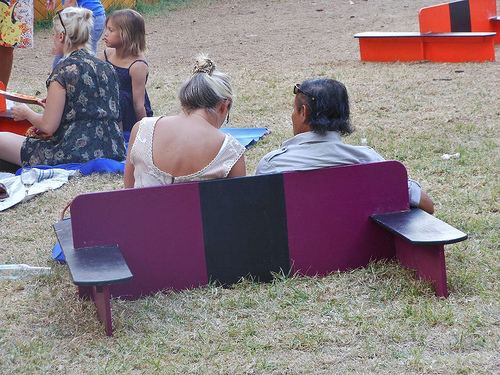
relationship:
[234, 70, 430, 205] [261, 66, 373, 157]
man has head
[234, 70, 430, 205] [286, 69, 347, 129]
man has glasses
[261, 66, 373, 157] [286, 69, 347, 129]
head has glasses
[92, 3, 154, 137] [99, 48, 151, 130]
girl has dress